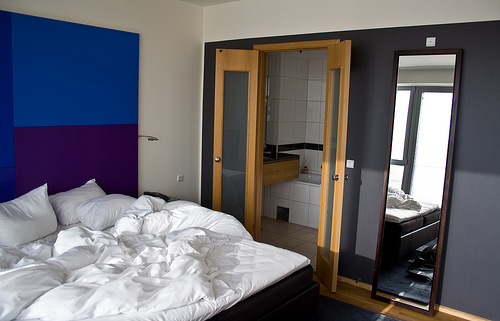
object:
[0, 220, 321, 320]
bed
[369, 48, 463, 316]
mirror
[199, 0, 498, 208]
wall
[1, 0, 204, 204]
wall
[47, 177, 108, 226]
pillows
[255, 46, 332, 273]
doors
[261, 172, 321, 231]
tub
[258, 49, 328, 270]
bathroom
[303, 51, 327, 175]
bathroom wall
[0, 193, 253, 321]
sheets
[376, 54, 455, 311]
reflection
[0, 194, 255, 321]
comforter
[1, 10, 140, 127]
blue wall decoration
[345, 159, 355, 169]
light switch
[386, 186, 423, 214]
reflection of bed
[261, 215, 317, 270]
floor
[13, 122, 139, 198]
purple wall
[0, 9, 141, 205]
headboard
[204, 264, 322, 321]
footboard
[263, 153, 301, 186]
counter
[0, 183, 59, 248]
pillow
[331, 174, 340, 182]
handle